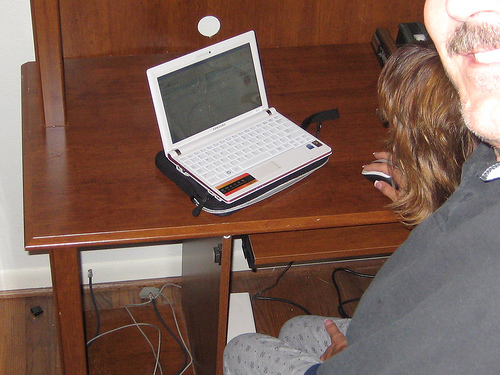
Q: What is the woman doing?
A: Looking on the computer.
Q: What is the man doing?
A: Smiling.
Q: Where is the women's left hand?
A: Between her legs.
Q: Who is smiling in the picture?
A: The man.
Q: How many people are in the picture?
A: Two.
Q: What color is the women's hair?
A: Brown.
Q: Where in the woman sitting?
A: At a desk.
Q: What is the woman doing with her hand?
A: Using a mouse.